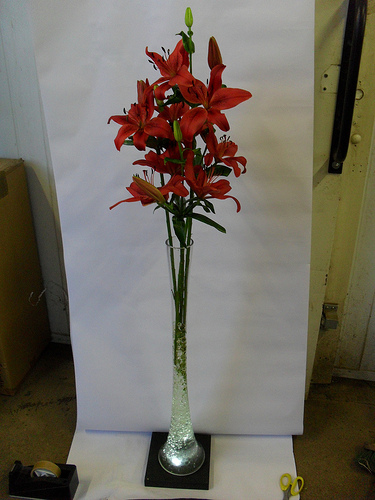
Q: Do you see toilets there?
A: No, there are no toilets.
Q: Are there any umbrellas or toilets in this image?
A: No, there are no toilets or umbrellas.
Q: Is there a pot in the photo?
A: No, there are no pots.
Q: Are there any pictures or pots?
A: No, there are no pots or pictures.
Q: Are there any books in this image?
A: No, there are no books.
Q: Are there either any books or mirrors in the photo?
A: No, there are no books or mirrors.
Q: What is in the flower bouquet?
A: The flower is in the flower bouquet.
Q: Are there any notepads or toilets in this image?
A: No, there are no toilets or notepads.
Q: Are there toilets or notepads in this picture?
A: No, there are no toilets or notepads.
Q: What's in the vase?
A: The flower is in the vase.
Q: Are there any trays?
A: No, there are no trays.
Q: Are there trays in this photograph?
A: No, there are no trays.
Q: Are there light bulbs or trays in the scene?
A: No, there are no trays or light bulbs.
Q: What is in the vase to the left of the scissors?
A: The flower is in the vase.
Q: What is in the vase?
A: The flower is in the vase.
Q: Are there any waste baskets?
A: No, there are no waste baskets.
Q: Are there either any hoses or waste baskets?
A: No, there are no waste baskets or hoses.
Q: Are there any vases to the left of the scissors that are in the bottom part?
A: Yes, there is a vase to the left of the scissors.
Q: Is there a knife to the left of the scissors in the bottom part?
A: No, there is a vase to the left of the scissors.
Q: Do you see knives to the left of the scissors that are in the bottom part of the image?
A: No, there is a vase to the left of the scissors.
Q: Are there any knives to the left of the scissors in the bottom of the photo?
A: No, there is a vase to the left of the scissors.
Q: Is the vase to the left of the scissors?
A: Yes, the vase is to the left of the scissors.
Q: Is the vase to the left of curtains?
A: No, the vase is to the left of the scissors.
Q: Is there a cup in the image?
A: No, there are no cups.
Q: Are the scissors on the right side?
A: Yes, the scissors are on the right of the image.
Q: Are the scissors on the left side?
A: No, the scissors are on the right of the image.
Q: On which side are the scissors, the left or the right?
A: The scissors are on the right of the image.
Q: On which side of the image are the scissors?
A: The scissors are on the right of the image.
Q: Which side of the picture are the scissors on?
A: The scissors are on the right of the image.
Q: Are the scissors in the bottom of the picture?
A: Yes, the scissors are in the bottom of the image.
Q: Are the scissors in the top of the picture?
A: No, the scissors are in the bottom of the image.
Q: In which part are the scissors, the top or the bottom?
A: The scissors are in the bottom of the image.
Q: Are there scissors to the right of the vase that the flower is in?
A: Yes, there are scissors to the right of the vase.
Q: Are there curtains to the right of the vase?
A: No, there are scissors to the right of the vase.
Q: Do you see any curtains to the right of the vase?
A: No, there are scissors to the right of the vase.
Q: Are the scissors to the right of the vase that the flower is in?
A: Yes, the scissors are to the right of the vase.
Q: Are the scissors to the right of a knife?
A: No, the scissors are to the right of the vase.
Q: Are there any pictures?
A: No, there are no pictures.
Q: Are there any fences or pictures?
A: No, there are no pictures or fences.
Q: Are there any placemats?
A: No, there are no placemats.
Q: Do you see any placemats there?
A: No, there are no placemats.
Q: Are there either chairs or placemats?
A: No, there are no placemats or chairs.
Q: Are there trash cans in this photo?
A: No, there are no trash cans.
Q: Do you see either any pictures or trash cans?
A: No, there are no trash cans or pictures.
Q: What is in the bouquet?
A: The flower is in the flower bouquet.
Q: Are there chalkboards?
A: No, there are no chalkboards.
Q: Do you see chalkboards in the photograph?
A: No, there are no chalkboards.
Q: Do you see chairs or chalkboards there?
A: No, there are no chalkboards or chairs.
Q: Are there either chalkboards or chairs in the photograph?
A: No, there are no chalkboards or chairs.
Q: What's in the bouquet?
A: The flower is in the bouquet.